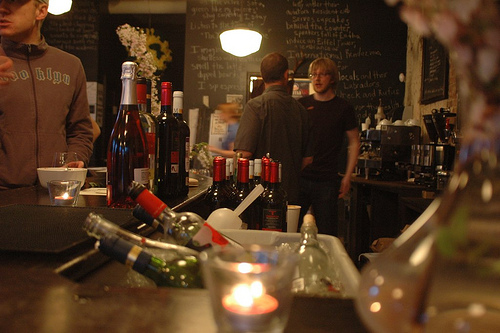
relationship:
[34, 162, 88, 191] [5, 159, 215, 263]
bowl on top of table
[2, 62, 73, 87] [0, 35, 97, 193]
lettering attached to hoodie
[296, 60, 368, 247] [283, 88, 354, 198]
man wearing shirt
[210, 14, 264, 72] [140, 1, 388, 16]
light attached to ceiling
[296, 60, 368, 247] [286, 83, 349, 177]
man wearing shirt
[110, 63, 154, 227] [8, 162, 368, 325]
bottle on bar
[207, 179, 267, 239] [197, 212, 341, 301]
scoop in ice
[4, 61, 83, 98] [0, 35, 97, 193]
brooklyn written on hoodie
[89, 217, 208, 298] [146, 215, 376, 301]
bottle sitting in a container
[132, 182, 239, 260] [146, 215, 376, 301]
bottle sitting in a container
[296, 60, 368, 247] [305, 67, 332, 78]
man wearing glasses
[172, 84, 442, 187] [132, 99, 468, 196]
writing on an object in background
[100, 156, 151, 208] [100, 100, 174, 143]
liquid red with silver top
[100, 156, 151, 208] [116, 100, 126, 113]
liquid red with silver top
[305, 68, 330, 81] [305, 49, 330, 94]
glasses on face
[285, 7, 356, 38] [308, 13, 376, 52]
chalkboard on walls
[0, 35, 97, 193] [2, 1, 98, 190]
hoodie on customer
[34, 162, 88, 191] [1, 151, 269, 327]
bowl on bar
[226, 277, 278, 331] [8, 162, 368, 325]
candle on bar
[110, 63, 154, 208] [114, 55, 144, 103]
bottle has top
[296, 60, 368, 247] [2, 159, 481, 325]
man talking behind bar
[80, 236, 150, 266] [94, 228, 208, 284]
top attached to bottle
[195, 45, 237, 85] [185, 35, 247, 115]
writing on top of chalkboard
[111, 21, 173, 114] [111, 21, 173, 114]
bouquet of bouquet